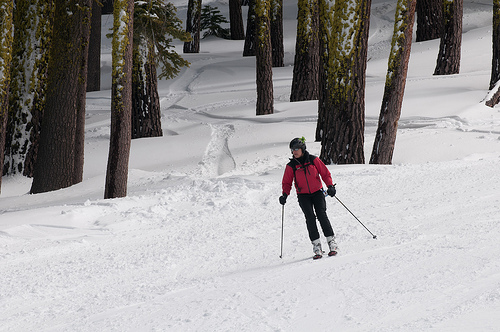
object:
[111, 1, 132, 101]
moss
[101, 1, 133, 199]
tree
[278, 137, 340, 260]
person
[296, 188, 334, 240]
pants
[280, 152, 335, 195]
jacket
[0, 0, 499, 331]
ground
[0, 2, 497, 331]
snow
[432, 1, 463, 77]
trees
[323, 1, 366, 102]
moss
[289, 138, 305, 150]
helmet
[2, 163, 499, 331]
main trail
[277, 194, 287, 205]
right hand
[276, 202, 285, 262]
ski pole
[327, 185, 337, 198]
left hand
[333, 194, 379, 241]
ski pole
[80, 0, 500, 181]
snow trail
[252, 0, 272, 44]
moss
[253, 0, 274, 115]
tree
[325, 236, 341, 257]
boot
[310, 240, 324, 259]
boot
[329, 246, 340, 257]
foot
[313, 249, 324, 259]
foot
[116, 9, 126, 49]
snow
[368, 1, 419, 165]
tree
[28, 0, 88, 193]
tree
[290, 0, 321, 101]
tree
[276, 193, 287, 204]
ski glove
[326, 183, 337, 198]
ski glove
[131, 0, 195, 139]
tree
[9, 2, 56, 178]
tree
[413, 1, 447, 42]
tree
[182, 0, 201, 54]
tree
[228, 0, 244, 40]
tree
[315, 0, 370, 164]
tree